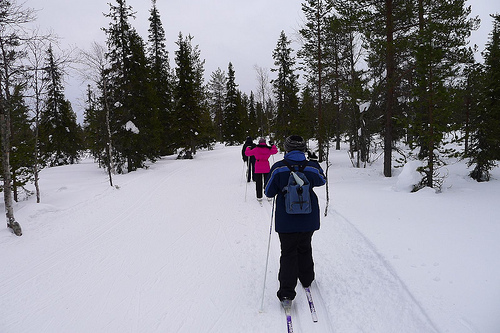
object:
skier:
[242, 136, 278, 199]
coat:
[245, 144, 278, 174]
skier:
[263, 132, 328, 306]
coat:
[265, 150, 328, 231]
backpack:
[282, 159, 312, 215]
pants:
[276, 231, 316, 300]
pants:
[253, 172, 272, 197]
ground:
[1, 127, 498, 330]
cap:
[282, 134, 307, 153]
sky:
[0, 1, 498, 121]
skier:
[241, 135, 257, 181]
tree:
[81, 43, 126, 187]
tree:
[142, 1, 180, 154]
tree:
[171, 30, 201, 154]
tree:
[35, 44, 78, 165]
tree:
[222, 63, 244, 146]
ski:
[281, 309, 295, 332]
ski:
[303, 286, 319, 323]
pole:
[260, 194, 277, 317]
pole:
[244, 157, 253, 200]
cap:
[258, 138, 267, 143]